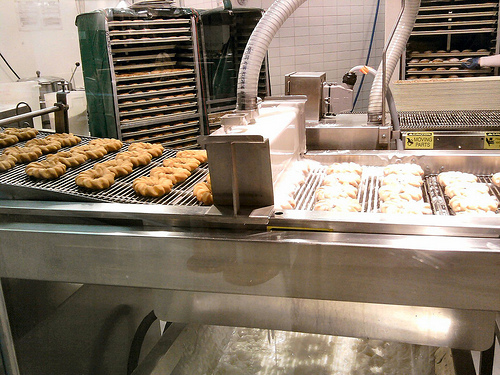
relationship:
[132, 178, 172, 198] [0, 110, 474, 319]
donut on machine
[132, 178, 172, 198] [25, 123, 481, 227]
donut on conveyor belt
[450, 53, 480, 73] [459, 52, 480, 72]
hand with glove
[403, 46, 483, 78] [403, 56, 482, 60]
racks of donuts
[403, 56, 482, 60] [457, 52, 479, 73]
donuts beside hand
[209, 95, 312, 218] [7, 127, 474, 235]
section of conveyor belt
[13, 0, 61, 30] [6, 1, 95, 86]
signs on wall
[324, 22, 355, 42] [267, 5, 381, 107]
tiles on wall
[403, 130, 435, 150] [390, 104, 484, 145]
sticker on conveyor belt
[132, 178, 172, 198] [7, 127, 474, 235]
donut on conveyor belt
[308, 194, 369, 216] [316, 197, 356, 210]
donut covered with powder sugar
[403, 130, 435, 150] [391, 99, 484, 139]
sticker on conveyor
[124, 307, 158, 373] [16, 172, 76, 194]
black hose under conveyor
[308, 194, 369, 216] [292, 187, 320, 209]
donut are on conveyor belt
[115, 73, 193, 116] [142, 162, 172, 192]
trays are stacked with donuts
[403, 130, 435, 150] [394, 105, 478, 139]
sticker are on machines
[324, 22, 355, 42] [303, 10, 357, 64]
tiles are on wall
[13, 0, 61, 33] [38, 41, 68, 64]
signs are on wall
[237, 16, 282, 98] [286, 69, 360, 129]
hoses are connected to machine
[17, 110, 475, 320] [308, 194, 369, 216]
machine icing donut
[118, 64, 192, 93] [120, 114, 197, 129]
doughnuts are stored in pans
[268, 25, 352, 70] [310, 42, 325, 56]
wall made of white tile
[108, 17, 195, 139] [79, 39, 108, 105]
rack has a cover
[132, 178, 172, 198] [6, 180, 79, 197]
donut are on a conveyor belt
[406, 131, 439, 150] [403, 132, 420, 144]
sticker has writing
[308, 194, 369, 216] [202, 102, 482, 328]
donut are on factory equipment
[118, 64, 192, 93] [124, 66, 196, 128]
doughnuts drying on racks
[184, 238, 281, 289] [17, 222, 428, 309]
reflection on silver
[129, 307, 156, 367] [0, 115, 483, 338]
black hose under silver conveyor